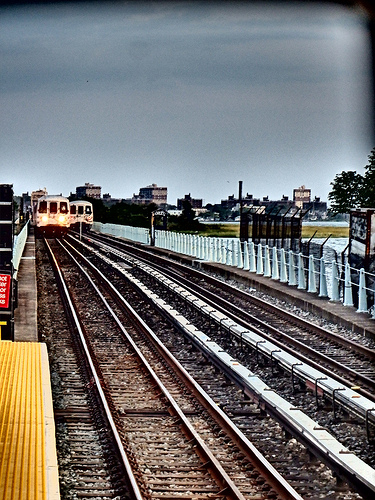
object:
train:
[33, 192, 71, 238]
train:
[69, 200, 94, 232]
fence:
[194, 237, 364, 284]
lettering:
[0, 282, 8, 286]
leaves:
[343, 178, 353, 189]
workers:
[3, 236, 45, 338]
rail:
[98, 215, 243, 266]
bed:
[66, 268, 279, 389]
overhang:
[0, 339, 64, 498]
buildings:
[75, 175, 328, 226]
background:
[29, 182, 306, 201]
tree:
[326, 145, 375, 221]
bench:
[0, 267, 19, 342]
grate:
[38, 287, 55, 343]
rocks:
[221, 382, 242, 410]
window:
[70, 204, 92, 215]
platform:
[13, 227, 38, 345]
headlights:
[41, 214, 67, 224]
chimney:
[238, 181, 243, 200]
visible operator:
[59, 198, 67, 212]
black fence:
[239, 200, 318, 255]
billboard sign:
[294, 190, 310, 198]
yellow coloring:
[0, 340, 45, 500]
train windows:
[37, 199, 69, 214]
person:
[61, 206, 66, 212]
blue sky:
[0, 4, 317, 155]